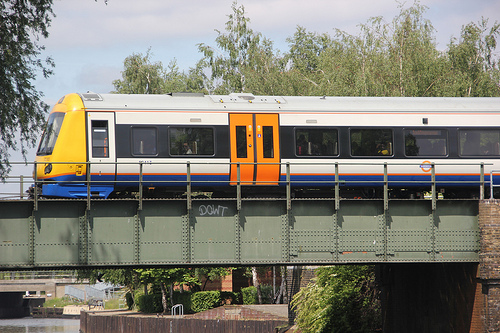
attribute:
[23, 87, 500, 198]
train — yellow, blue, white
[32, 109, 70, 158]
windshield — large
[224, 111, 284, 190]
door — orange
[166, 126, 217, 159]
passenger window — large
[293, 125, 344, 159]
passenger window — large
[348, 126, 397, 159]
passenger window — large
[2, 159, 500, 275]
bridge — metal, green, olive, painted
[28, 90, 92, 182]
train front — yellow, blue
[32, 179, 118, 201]
bumper — blue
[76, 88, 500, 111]
roof — white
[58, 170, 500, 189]
lower train — blue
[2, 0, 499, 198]
sky — blue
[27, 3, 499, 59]
clouds — white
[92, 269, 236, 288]
leaves — green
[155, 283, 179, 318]
tree — brown, tall, green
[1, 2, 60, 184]
tree — tall, green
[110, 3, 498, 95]
tree — tall, green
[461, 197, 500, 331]
base — brick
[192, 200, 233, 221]
graffiti — white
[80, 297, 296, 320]
dock — concrete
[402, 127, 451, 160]
passenger window — large